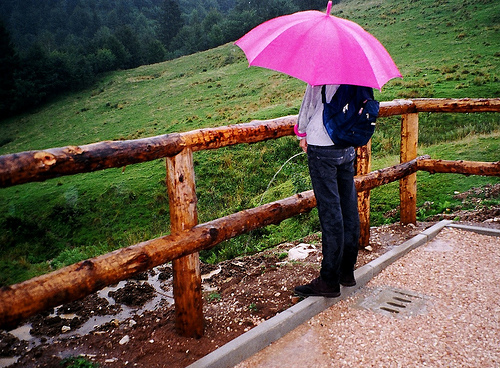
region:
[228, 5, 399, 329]
a person has an open pink umbrella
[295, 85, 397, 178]
the person has a blue backpack on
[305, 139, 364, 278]
blue jeans are on the man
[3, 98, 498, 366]
a wooden fence is around the overlook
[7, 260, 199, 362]
ice is around the overlook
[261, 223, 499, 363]
the gravel is surrounded by a curb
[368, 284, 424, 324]
a cement drain is in the gravel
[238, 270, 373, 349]
the curb is poured cement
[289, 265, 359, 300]
the man has black shoes on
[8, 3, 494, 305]
a forest is behind the clearing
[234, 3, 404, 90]
a pink umbrella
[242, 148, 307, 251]
a stream of urine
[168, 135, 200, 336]
a thick wooden post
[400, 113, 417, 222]
a thick wooden post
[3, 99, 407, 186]
a thick wooden post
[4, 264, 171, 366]
dirt covered with water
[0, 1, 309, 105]
a dense thicket of trees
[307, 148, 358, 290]
a person's jeans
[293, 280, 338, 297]
black shoe on a foot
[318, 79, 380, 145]
a blue backpack on a person's back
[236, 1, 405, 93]
pink fabric umbrella in hand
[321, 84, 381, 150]
blue bag on back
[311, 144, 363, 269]
dark blue denim jeans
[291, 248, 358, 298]
black suede ankle boots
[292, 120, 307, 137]
pink handle of umbrella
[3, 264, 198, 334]
frozen snow on ground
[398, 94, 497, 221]
wood painted log fence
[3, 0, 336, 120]
trees with green leaves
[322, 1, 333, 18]
pink tip on umbrella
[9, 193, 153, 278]
green weeds on ground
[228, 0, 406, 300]
person holding pink umbrella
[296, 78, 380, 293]
person carrying backpack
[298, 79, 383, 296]
person wearing black jeans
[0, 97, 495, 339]
fence is brown wood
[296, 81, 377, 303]
person wearing white shirt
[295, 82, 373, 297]
person standing on sidewalk ledge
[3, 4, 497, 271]
grass field behind wooden fence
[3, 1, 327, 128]
trees behind grass field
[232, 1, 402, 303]
pink umbrella covering person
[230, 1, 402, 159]
pink umbrella covering backpack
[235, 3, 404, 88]
top of a pink umbrella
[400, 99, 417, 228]
a thick wooden post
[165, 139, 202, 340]
a thick wooden post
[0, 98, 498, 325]
a fence made of thick wooden logs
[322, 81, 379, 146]
backpack on a person's back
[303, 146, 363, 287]
a pair of jeans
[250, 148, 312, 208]
a man is peeing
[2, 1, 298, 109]
trees on a hillside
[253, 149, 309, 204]
a stream of pee